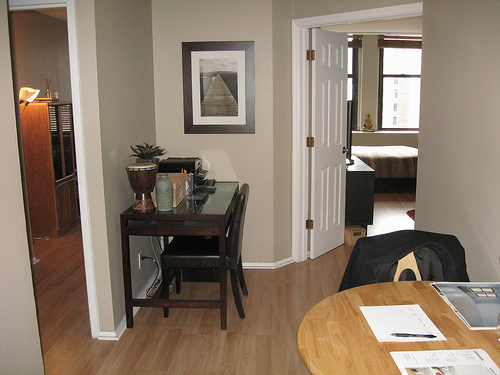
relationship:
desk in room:
[119, 143, 241, 332] [100, 4, 500, 374]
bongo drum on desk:
[123, 156, 162, 219] [119, 143, 241, 332]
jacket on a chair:
[336, 231, 481, 300] [337, 224, 478, 305]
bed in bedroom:
[347, 135, 419, 177] [316, 16, 419, 254]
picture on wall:
[175, 34, 258, 140] [149, 1, 281, 270]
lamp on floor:
[9, 85, 45, 124] [34, 236, 82, 323]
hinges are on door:
[302, 43, 322, 246] [305, 26, 348, 262]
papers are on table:
[355, 281, 500, 374] [297, 281, 499, 373]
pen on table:
[389, 329, 444, 344] [297, 281, 499, 373]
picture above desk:
[175, 34, 258, 140] [119, 143, 241, 332]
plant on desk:
[128, 140, 169, 171] [119, 143, 241, 332]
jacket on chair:
[336, 231, 481, 300] [337, 224, 478, 305]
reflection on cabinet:
[50, 106, 79, 176] [13, 89, 82, 246]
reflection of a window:
[50, 106, 79, 176] [42, 105, 82, 136]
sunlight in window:
[387, 50, 414, 123] [345, 40, 428, 140]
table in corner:
[297, 281, 499, 373] [455, 281, 500, 374]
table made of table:
[297, 281, 499, 373] [294, 281, 499, 373]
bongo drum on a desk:
[123, 156, 162, 219] [119, 143, 241, 332]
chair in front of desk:
[161, 181, 260, 310] [119, 143, 241, 332]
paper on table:
[357, 296, 445, 347] [297, 281, 499, 373]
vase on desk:
[153, 169, 179, 218] [119, 143, 241, 332]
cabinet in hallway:
[13, 89, 82, 246] [0, 4, 91, 353]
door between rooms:
[305, 26, 348, 262] [91, 4, 499, 374]